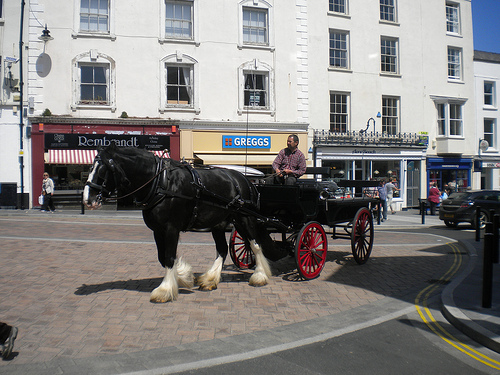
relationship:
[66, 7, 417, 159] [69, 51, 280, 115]
building has windows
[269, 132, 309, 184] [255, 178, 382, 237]
man on carriage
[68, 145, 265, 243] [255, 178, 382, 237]
horse pulling carriage